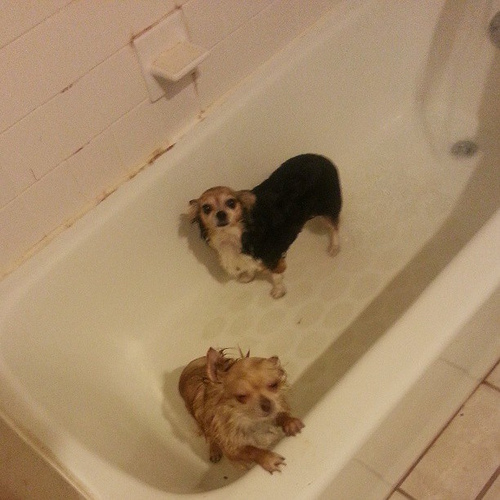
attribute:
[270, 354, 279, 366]
ear — small wet dog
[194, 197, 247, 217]
eyes — black, small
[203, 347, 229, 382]
dog ear — small wet dog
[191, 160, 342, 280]
dog — tan, wet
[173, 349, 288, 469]
dog —  brown , black 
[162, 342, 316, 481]
dog — brown ,  wet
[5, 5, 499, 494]
bathtub — white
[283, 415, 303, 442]
paw — small wet dog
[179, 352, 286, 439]
dog — small water soaked 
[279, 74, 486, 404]
bathtub — white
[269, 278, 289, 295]
paw — small wet dog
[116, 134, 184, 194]
grout — discolored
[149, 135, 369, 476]
dogs — looking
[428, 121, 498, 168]
drain — silver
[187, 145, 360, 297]
dog — fluffy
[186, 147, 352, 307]
dog — black, tan, looking up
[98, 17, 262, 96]
holder — white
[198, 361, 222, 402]
ear — small wet dog